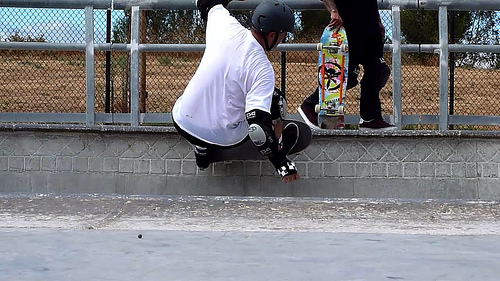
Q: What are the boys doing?
A: Skating.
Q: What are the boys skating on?
A: Skate boards.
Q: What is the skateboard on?
A: The wall.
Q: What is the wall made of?
A: Stone.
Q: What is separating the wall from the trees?
A: A fence.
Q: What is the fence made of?
A: Metal.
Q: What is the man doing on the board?
A: A trick.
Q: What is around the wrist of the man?
A: An accesory.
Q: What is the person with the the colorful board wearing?
A: All black.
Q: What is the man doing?
A: A skateboard trick.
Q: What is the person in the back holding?
A: A skateboard.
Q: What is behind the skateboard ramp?
A: A fence.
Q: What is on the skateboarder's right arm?
A: Protective padding.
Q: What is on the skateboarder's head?
A: Protective helmet.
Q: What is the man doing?
A: Skateboarding.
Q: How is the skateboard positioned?
A: On the wall.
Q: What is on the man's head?
A: A helmet.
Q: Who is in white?
A: A man.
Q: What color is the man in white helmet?
A: Black.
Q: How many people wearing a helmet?
A: One.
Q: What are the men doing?
A: Skateboarding.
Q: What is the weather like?
A: Clear skies.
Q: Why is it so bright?
A: Sunny.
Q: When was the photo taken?
A: Day time.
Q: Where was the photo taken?
A: At a skateboarding park.